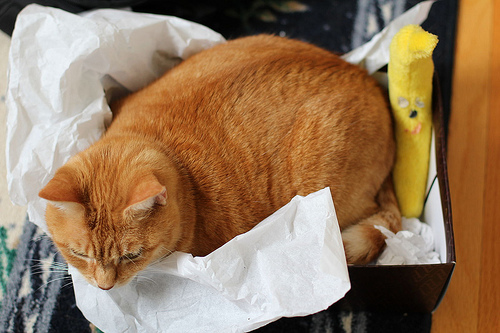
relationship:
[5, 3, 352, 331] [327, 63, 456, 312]
paper in box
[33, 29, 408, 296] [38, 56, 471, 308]
cat in a box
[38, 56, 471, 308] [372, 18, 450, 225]
box with toy